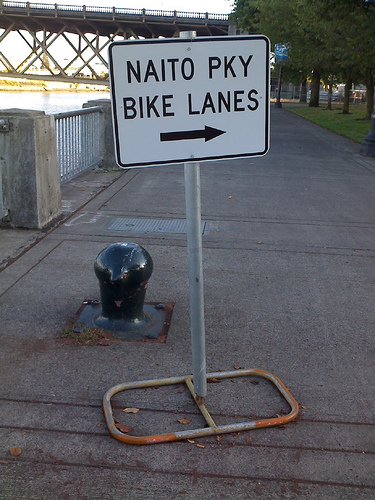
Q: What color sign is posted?
A: White.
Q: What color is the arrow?
A: Black.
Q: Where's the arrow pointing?
A: To the right.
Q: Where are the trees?
A: Upper right.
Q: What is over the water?
A: A bridge.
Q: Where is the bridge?
A: Over the water.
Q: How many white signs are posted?
A: One.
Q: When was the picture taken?
A: Daytime.